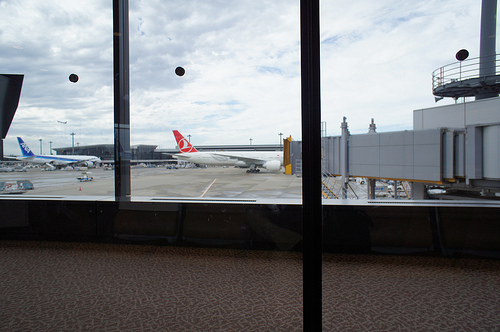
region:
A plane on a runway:
[166, 124, 287, 184]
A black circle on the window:
[173, 65, 188, 80]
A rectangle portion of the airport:
[286, 127, 476, 189]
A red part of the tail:
[173, 128, 196, 152]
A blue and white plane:
[18, 135, 108, 172]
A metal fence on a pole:
[429, 55, 499, 95]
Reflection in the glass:
[112, 193, 376, 258]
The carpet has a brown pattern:
[76, 264, 212, 324]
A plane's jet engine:
[261, 158, 283, 175]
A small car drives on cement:
[76, 167, 94, 184]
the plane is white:
[169, 148, 274, 178]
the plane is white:
[26, 146, 128, 171]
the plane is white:
[185, 133, 293, 187]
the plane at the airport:
[151, 103, 315, 201]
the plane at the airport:
[7, 129, 112, 186]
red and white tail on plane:
[163, 127, 196, 150]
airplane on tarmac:
[166, 126, 291, 179]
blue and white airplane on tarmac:
[6, 133, 103, 172]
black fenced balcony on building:
[423, 49, 498, 96]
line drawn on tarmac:
[190, 172, 222, 204]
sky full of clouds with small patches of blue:
[2, 2, 482, 139]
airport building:
[49, 138, 189, 168]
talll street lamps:
[63, 129, 81, 159]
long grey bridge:
[141, 135, 301, 156]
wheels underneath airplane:
[241, 165, 264, 177]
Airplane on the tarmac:
[154, 131, 249, 176]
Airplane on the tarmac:
[16, 140, 93, 188]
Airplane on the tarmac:
[182, 115, 279, 197]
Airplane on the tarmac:
[43, 143, 111, 193]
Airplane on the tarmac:
[156, 108, 241, 195]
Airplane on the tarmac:
[61, 143, 101, 180]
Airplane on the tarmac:
[36, 148, 132, 178]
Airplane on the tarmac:
[51, 141, 116, 171]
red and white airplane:
[165, 136, 265, 180]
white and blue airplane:
[15, 133, 92, 174]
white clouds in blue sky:
[18, 3, 60, 39]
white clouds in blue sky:
[32, 91, 79, 122]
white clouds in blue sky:
[134, 87, 200, 148]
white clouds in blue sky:
[219, 80, 260, 126]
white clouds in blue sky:
[134, 6, 176, 39]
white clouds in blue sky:
[188, 12, 265, 54]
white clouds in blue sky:
[345, 12, 394, 58]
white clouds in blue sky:
[337, 61, 384, 100]